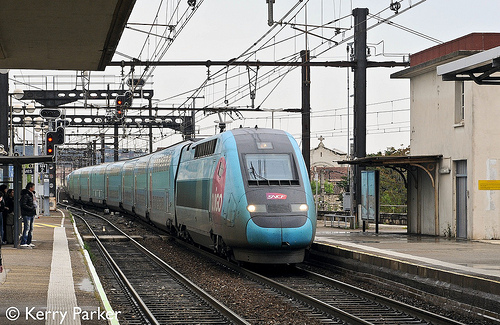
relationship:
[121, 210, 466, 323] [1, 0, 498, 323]
track at train depot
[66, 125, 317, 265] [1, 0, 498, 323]
train at train depot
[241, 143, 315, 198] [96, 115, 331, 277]
window on train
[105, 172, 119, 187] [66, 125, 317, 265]
window of train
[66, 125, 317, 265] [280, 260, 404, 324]
train on track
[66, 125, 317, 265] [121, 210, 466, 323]
train on track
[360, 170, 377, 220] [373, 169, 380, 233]
sign attached to pole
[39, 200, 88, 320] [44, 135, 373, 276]
line beside train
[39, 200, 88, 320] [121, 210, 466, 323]
line beside track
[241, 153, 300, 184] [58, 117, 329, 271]
window of a train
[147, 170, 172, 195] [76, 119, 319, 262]
window of a train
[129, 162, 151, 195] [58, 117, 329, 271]
window of a train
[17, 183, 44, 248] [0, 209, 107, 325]
man on a loading platform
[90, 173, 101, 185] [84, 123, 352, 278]
window of train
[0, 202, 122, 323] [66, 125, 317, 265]
loading platform for train